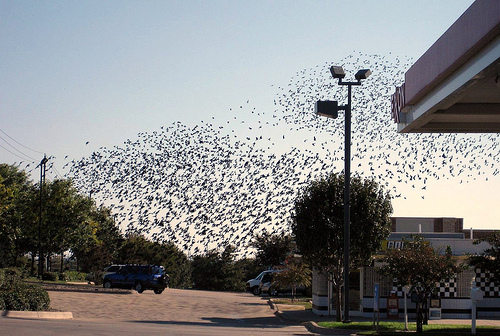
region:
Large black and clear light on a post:
[325, 59, 345, 86]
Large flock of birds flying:
[51, 73, 484, 257]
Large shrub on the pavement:
[6, 254, 56, 324]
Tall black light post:
[311, 57, 365, 324]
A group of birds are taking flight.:
[48, 111, 391, 264]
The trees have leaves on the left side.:
[1, 160, 114, 312]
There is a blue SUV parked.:
[104, 263, 171, 298]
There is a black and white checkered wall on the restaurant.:
[389, 256, 460, 303]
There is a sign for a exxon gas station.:
[381, 82, 420, 125]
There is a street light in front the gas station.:
[312, 57, 372, 327]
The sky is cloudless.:
[6, 5, 437, 82]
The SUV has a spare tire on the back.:
[159, 270, 174, 287]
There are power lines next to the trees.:
[0, 127, 50, 173]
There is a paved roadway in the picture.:
[9, 312, 309, 333]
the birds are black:
[153, 148, 215, 174]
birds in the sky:
[148, 138, 220, 193]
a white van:
[241, 274, 256, 291]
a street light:
[327, 52, 370, 86]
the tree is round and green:
[298, 205, 326, 242]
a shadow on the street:
[209, 310, 238, 333]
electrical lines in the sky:
[9, 140, 28, 158]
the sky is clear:
[62, 48, 134, 90]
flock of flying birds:
[52, 60, 492, 262]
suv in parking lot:
[103, 261, 164, 291]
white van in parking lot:
[248, 273, 281, 291]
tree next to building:
[293, 172, 385, 322]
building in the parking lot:
[310, 216, 499, 323]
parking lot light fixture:
[310, 59, 369, 318]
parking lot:
[19, 260, 307, 335]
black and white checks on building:
[398, 266, 497, 301]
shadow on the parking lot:
[132, 314, 276, 334]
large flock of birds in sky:
[68, 50, 498, 254]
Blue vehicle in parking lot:
[104, 260, 168, 296]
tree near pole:
[298, 148, 392, 326]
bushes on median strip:
[8, 280, 73, 335]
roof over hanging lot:
[386, 10, 498, 131]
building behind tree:
[316, 203, 495, 334]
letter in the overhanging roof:
[382, 83, 414, 118]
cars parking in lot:
[232, 260, 302, 305]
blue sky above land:
[36, 21, 200, 108]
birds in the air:
[110, 88, 290, 233]